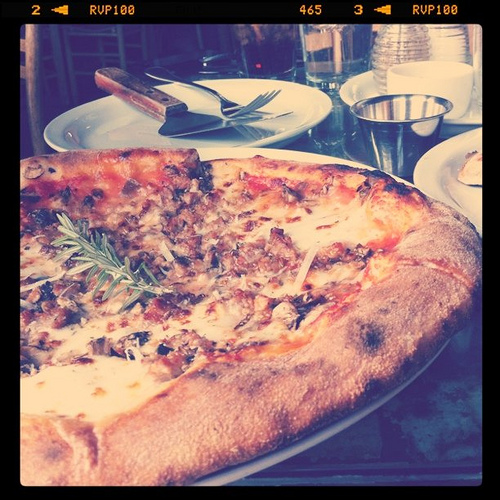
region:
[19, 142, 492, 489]
pizza on white plate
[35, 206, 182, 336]
green leaf seasoning on pizza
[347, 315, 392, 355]
brown burn mark on pizza crust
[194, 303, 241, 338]
white cheese on top of pizza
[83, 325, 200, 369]
brown topping on pizza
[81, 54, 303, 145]
two utensils on white plate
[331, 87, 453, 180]
small metal container on table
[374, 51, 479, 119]
small white bowl on table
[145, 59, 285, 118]
metal fork on white plate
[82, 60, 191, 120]
brown handle on metal spatula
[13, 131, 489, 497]
A pizza on a pizza pan.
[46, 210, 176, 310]
A sprig of terragon on top of the pizza.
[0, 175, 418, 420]
Melted cheese on top of the pizza.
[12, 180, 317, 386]
Black olives on top of the pizza.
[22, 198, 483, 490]
A tan crispy pizza crust.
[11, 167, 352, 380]
Bits of meat on top of the pizza.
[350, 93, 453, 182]
A metal container sitting next to the pizza.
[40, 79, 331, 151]
A white plate sitting next to the pizza.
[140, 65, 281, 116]
A silver fork on top of the white plate.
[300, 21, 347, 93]
An empty glass cup on top of the table.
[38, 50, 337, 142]
pizza server and fork on a plate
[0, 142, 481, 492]
oven grilled pizza on a plate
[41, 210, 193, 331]
sprig of rosemary on a pizza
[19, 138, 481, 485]
large pizza on a plate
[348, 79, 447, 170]
empty stainless steel ramekin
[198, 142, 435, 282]
sightly burned slice of pizza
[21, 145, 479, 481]
wood fire oven baked pizza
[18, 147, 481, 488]
pizza with a cutting of rosemary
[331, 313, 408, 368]
burned spot on a pizza crust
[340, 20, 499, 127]
condiments sitting on a plate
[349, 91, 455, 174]
small silver serving bowl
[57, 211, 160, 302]
seasoning on the pizza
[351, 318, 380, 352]
black spot on the crust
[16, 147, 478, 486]
the pizza has been cooked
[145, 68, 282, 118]
metal fork on the plate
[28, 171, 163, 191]
pizza sauce by the crust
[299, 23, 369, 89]
clear drinking glass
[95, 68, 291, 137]
serving spatula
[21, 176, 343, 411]
pizza toppings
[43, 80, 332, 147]
small round plate with utensils on it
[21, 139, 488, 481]
pizza on white plate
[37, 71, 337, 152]
round white dinner plate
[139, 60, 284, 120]
silver tone dinner fork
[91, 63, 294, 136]
wood and metal spatula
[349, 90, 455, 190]
metal cup on table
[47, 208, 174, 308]
sprig of rosemary on pizza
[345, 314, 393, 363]
charred spot on crust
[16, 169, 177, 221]
tomato sauce on pizza slice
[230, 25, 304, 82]
beverage in clear glass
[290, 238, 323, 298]
piece of onion on pizza